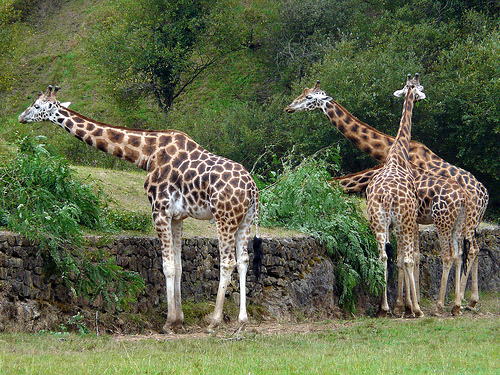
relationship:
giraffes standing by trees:
[25, 77, 490, 334] [52, 20, 483, 151]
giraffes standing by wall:
[25, 77, 490, 334] [18, 232, 331, 326]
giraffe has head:
[19, 84, 277, 335] [21, 92, 50, 123]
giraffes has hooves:
[25, 77, 490, 334] [160, 315, 265, 338]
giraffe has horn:
[19, 84, 277, 335] [45, 84, 61, 97]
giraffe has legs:
[19, 84, 277, 335] [208, 228, 256, 336]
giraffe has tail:
[19, 84, 277, 335] [251, 202, 267, 253]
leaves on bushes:
[292, 189, 317, 212] [276, 176, 388, 325]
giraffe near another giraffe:
[19, 84, 277, 335] [278, 83, 489, 223]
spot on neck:
[333, 110, 342, 125] [328, 101, 391, 154]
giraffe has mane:
[19, 84, 277, 335] [64, 110, 158, 136]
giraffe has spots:
[19, 84, 277, 335] [159, 161, 218, 195]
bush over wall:
[258, 146, 364, 269] [18, 232, 331, 326]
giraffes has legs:
[25, 77, 490, 334] [208, 228, 256, 336]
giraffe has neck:
[278, 83, 489, 223] [328, 101, 391, 154]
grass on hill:
[38, 155, 275, 213] [40, 20, 499, 180]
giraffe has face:
[19, 84, 277, 335] [31, 105, 53, 119]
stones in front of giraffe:
[13, 256, 49, 300] [19, 84, 277, 335]